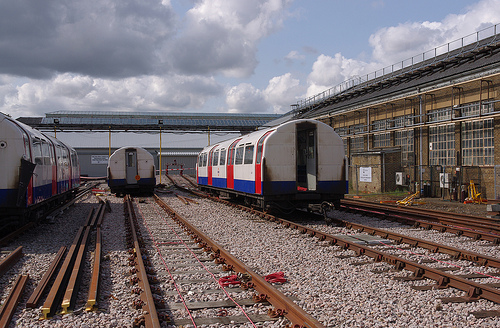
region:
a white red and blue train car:
[232, 117, 349, 217]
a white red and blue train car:
[207, 132, 238, 198]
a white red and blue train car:
[192, 134, 214, 187]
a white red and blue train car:
[107, 142, 152, 194]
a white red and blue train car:
[0, 115, 50, 222]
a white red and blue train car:
[52, 134, 71, 197]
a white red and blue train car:
[64, 143, 81, 189]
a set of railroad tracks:
[112, 179, 313, 326]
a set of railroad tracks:
[167, 167, 497, 307]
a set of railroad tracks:
[335, 188, 497, 249]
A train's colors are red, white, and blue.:
[190, 113, 360, 221]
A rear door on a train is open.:
[291, 116, 323, 202]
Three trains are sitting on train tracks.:
[0, 95, 359, 257]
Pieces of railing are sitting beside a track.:
[0, 191, 120, 326]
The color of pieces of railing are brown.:
[0, 189, 118, 326]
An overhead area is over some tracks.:
[11, 81, 293, 146]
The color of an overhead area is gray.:
[20, 94, 285, 148]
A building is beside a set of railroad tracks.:
[287, 13, 499, 212]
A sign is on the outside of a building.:
[354, 161, 378, 188]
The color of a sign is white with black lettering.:
[354, 163, 374, 185]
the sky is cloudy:
[0, 0, 496, 115]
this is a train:
[185, 117, 346, 197]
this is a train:
[97, 145, 152, 190]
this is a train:
[1, 110, 81, 205]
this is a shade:
[36, 110, 278, 132]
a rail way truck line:
[198, 210, 269, 267]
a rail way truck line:
[131, 212, 241, 324]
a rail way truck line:
[337, 216, 492, 321]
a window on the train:
[241, 146, 251, 159]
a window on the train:
[216, 144, 228, 167]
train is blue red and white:
[195, 120, 365, 202]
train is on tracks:
[125, 170, 498, 325]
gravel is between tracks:
[19, 173, 499, 326]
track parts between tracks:
[3, 180, 118, 326]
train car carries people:
[193, 118, 357, 208]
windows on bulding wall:
[341, 101, 498, 164]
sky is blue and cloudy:
[1, 1, 499, 111]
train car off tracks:
[103, 148, 165, 200]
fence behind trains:
[36, 124, 244, 183]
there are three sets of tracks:
[2, 181, 498, 327]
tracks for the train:
[283, 210, 435, 326]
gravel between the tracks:
[216, 228, 280, 267]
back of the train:
[252, 107, 351, 223]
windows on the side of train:
[190, 124, 262, 179]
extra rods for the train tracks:
[46, 206, 114, 318]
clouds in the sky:
[203, 46, 340, 93]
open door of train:
[276, 119, 328, 206]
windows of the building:
[371, 100, 488, 191]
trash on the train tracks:
[196, 262, 306, 299]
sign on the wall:
[326, 160, 373, 202]